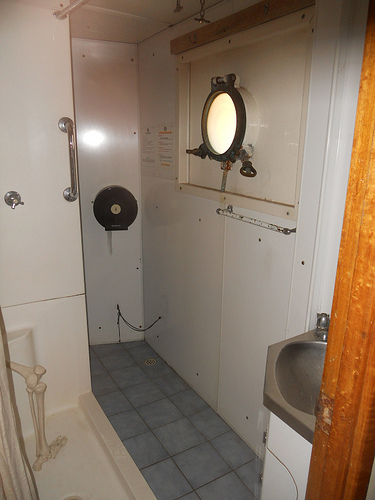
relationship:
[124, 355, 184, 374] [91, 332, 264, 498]
drain on floor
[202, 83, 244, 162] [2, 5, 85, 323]
port hole in wall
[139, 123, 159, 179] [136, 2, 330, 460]
sign on wall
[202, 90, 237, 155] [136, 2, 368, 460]
port hole on wall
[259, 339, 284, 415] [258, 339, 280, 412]
sink edge on sink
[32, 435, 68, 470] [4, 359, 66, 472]
foot on skeleton`s leg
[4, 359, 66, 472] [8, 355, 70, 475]
skeleton`s leg on skeleton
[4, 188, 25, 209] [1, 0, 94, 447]
tap valve on wall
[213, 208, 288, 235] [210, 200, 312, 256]
paint on towel bar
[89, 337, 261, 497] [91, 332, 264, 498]
grout on floor